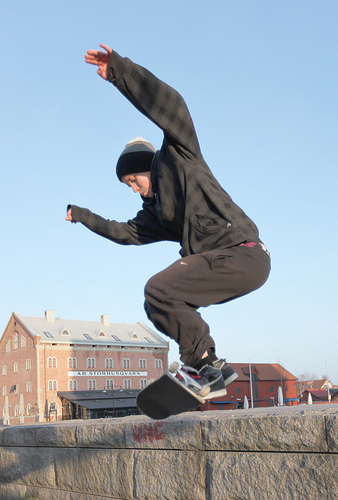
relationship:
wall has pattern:
[30, 351, 114, 393] [1, 409, 326, 499]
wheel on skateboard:
[166, 359, 181, 376] [124, 366, 216, 423]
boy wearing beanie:
[61, 40, 271, 397] [112, 138, 157, 177]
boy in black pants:
[43, 31, 277, 397] [142, 243, 271, 369]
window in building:
[74, 344, 103, 359] [29, 300, 180, 399]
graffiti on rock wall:
[133, 421, 165, 443] [0, 400, 337, 498]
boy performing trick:
[61, 40, 271, 397] [100, 334, 253, 433]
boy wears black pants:
[61, 40, 271, 397] [141, 243, 271, 369]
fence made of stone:
[0, 402, 336, 498] [54, 449, 125, 498]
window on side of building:
[67, 356, 78, 369] [0, 308, 168, 435]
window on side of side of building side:
[138, 357, 148, 370] [31, 346, 172, 423]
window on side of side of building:
[45, 355, 58, 368] [1, 307, 172, 422]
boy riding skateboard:
[61, 40, 271, 397] [126, 366, 207, 426]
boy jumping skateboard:
[61, 40, 271, 397] [107, 370, 225, 417]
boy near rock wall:
[61, 40, 271, 397] [0, 400, 337, 498]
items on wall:
[262, 385, 277, 392] [256, 382, 278, 402]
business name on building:
[68, 370, 146, 376] [0, 308, 168, 435]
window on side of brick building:
[48, 379, 58, 392] [2, 309, 171, 426]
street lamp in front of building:
[100, 380, 126, 420] [55, 383, 161, 419]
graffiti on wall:
[133, 421, 165, 443] [3, 402, 327, 497]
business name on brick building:
[68, 370, 146, 376] [2, 309, 169, 427]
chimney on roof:
[41, 306, 56, 323] [13, 311, 168, 345]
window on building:
[67, 356, 78, 369] [10, 307, 115, 390]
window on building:
[84, 355, 98, 370] [10, 307, 115, 390]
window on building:
[118, 358, 133, 370] [10, 307, 115, 390]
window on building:
[134, 357, 148, 371] [10, 307, 115, 390]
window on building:
[42, 379, 59, 393] [10, 307, 115, 390]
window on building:
[66, 354, 78, 371] [1, 307, 172, 422]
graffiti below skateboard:
[128, 422, 163, 448] [119, 374, 206, 421]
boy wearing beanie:
[61, 40, 271, 397] [116, 137, 157, 183]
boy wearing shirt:
[61, 40, 271, 397] [67, 48, 263, 255]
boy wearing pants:
[61, 40, 271, 397] [143, 245, 272, 367]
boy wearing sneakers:
[61, 40, 271, 397] [211, 357, 238, 385]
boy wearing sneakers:
[61, 40, 271, 397] [177, 366, 227, 398]